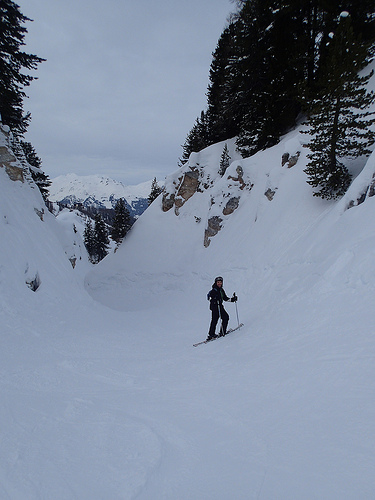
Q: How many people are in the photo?
A: One.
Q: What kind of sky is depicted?
A: Overcast.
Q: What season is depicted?
A: Winter.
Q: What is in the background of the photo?
A: Mountains.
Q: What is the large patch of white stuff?
A: Snow.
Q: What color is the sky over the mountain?
A: Gray.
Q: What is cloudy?
A: The sky.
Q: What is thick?
A: The snow.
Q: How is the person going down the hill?
A: On skis.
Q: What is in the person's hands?
A: Ski poles.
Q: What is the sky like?
A: Grey and cloudy.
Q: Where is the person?
A: On a ski trail.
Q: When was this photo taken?
A: Daytime.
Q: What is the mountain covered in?
A: Snow.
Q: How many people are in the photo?
A: One.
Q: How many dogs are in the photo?
A: None.